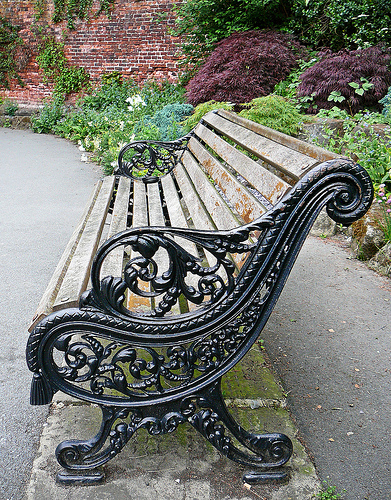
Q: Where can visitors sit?
A: Bench.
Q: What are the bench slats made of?
A: Wood.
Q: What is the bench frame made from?
A: Metal.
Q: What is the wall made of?
A: Brick.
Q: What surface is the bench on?
A: Concrete.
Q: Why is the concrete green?
A: Mold.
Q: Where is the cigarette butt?
A: By the back bench foot.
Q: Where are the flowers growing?
A: Garden.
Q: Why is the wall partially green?
A: Vines.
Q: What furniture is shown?
A: Bench.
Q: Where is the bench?
A: Park.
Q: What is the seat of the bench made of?
A: Wood.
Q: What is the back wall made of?
A: Brick.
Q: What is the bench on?
A: Slab.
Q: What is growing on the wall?
A: Plants.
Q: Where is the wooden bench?
A: In a garden.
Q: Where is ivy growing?
A: On brick wall.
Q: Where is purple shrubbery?
A: In background on right.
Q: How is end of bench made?
A: Ornate scrollwork.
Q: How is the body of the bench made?
A: Out of wood.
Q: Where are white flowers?
A: Between wall and bench.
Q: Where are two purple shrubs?
A: On right side in background.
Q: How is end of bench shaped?
A: Curved.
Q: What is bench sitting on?
A: A concrete pad.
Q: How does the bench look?
A: Wood looks faded.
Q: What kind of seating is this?
A: Bench.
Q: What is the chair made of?
A: Wood and metal.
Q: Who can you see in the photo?
A: No one.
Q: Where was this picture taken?
A: Park.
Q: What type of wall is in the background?
A: Brick wall.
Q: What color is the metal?
A: Black.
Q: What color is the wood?
A: Brown.